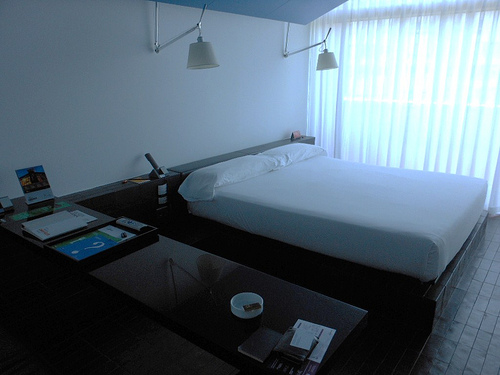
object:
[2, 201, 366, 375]
table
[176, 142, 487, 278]
bedspread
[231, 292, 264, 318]
bowl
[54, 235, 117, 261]
file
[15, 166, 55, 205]
calender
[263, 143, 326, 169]
pillows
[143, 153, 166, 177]
remote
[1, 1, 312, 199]
wall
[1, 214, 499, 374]
floor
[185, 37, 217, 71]
lamp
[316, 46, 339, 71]
lamp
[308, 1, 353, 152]
curtains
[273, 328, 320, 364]
wallet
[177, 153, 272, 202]
pillow cases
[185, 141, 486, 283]
bed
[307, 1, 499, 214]
window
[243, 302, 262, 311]
matches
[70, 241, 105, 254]
question mark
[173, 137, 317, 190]
headboard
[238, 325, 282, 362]
book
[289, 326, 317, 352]
business card